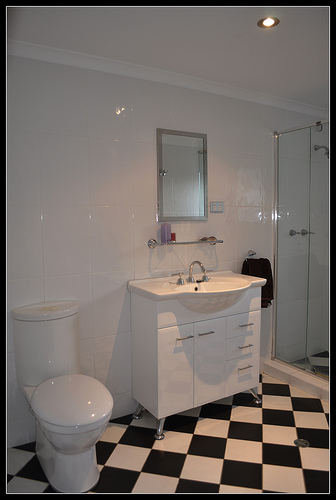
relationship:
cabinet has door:
[158, 310, 260, 394] [161, 332, 190, 414]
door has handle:
[161, 332, 190, 414] [179, 337, 192, 342]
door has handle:
[161, 332, 190, 414] [202, 333, 208, 337]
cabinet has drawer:
[158, 310, 260, 394] [230, 319, 261, 333]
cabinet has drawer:
[158, 310, 260, 394] [231, 342, 256, 356]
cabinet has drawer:
[158, 310, 260, 394] [232, 363, 257, 388]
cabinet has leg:
[158, 310, 260, 394] [154, 420, 163, 439]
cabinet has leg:
[158, 310, 260, 394] [251, 391, 261, 403]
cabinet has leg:
[158, 310, 260, 394] [136, 407, 144, 415]